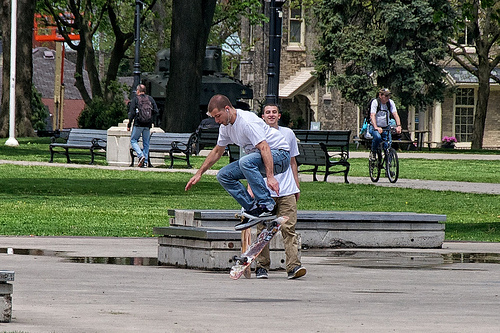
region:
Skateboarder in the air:
[186, 93, 296, 232]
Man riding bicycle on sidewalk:
[354, 83, 414, 189]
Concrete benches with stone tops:
[153, 205, 466, 282]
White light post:
[1, 0, 29, 152]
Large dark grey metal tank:
[126, 37, 266, 137]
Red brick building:
[13, 59, 111, 139]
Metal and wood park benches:
[43, 121, 363, 184]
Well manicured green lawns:
[1, 107, 493, 249]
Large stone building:
[233, 2, 498, 159]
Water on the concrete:
[4, 227, 499, 279]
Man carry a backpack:
[117, 79, 164, 173]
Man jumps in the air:
[182, 89, 294, 247]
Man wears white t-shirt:
[185, 87, 296, 239]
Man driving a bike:
[351, 80, 408, 190]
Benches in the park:
[37, 123, 359, 183]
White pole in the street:
[3, 0, 25, 150]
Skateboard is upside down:
[221, 213, 289, 285]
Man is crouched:
[176, 86, 298, 233]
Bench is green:
[43, 119, 115, 165]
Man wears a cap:
[346, 76, 414, 195]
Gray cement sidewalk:
[48, 261, 208, 331]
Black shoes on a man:
[226, 194, 301, 246]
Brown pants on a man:
[237, 191, 304, 308]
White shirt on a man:
[200, 94, 298, 200]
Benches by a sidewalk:
[51, 111, 205, 178]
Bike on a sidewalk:
[344, 82, 411, 194]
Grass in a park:
[12, 157, 169, 247]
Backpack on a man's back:
[125, 78, 157, 121]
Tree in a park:
[313, 8, 439, 162]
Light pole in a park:
[259, 20, 294, 131]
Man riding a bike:
[356, 83, 413, 184]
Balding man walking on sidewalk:
[118, 74, 160, 173]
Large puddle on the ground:
[309, 240, 497, 291]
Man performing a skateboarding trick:
[178, 85, 295, 284]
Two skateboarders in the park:
[158, 1, 358, 323]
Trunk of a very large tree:
[149, 0, 221, 135]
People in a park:
[36, 1, 494, 331]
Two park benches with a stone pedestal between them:
[44, 120, 198, 168]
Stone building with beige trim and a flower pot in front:
[233, 0, 498, 155]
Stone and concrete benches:
[148, 196, 455, 270]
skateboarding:
[191, 89, 322, 290]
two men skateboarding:
[174, 89, 331, 292]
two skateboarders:
[179, 86, 335, 288]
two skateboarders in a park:
[56, 86, 436, 332]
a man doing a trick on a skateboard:
[178, 86, 298, 293]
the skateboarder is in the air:
[176, 91, 294, 278]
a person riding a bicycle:
[360, 81, 409, 183]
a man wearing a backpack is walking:
[124, 78, 161, 178]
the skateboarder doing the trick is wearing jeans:
[175, 91, 294, 269]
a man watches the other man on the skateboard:
[251, 98, 313, 279]